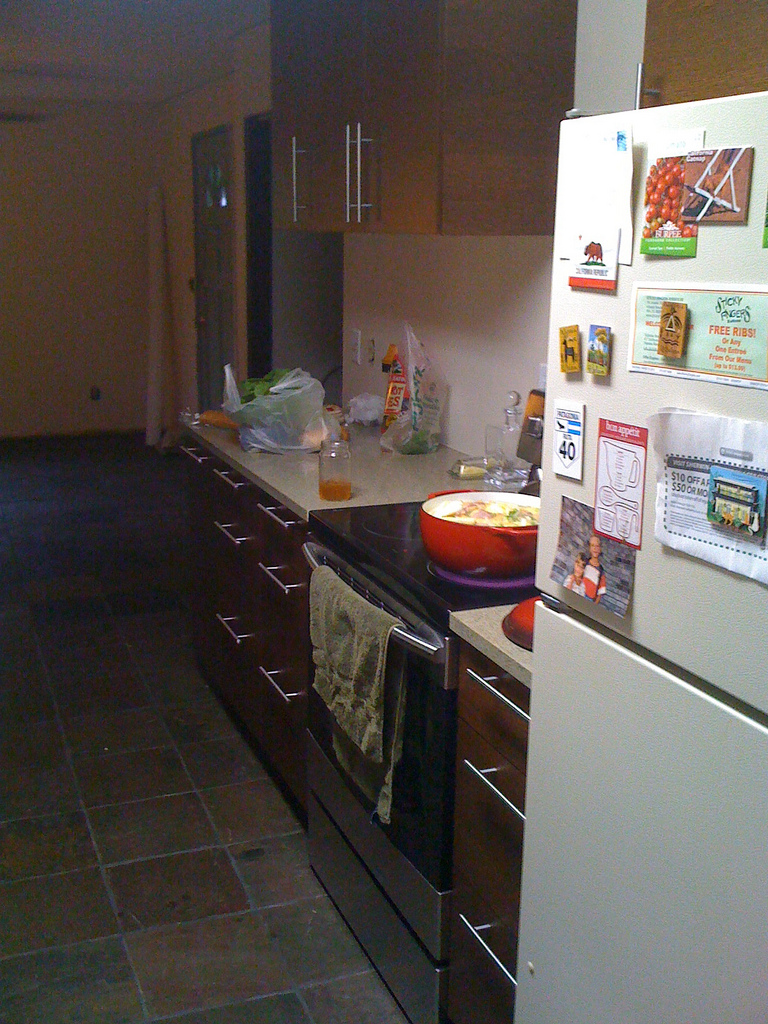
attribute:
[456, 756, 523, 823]
handle — silver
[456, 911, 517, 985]
handle — silver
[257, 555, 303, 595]
handle — silver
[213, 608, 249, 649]
handle — silver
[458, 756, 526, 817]
handle — silver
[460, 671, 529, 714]
handle — silver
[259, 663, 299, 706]
handle — silver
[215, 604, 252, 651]
handle — silver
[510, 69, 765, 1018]
refrigerator — white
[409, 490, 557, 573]
pot — large, orange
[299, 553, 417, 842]
towel — olive green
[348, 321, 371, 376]
outlet — white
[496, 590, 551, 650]
top — orange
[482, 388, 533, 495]
bottle — see through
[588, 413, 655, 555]
paper — red, white